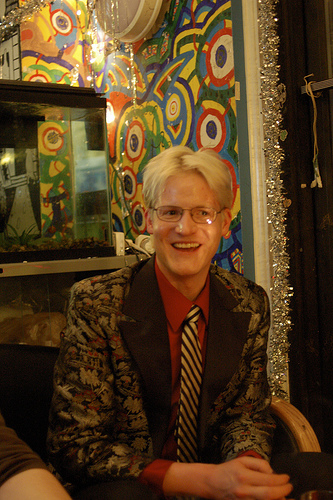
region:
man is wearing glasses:
[146, 204, 230, 225]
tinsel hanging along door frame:
[256, 0, 295, 399]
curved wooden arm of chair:
[267, 393, 319, 466]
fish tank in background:
[0, 267, 115, 352]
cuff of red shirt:
[137, 457, 194, 498]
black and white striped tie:
[178, 301, 205, 473]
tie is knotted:
[180, 301, 202, 324]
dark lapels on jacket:
[123, 257, 245, 454]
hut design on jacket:
[66, 341, 111, 376]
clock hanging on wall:
[94, 0, 171, 46]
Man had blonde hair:
[144, 141, 234, 207]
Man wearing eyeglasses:
[152, 205, 226, 224]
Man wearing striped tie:
[176, 302, 203, 461]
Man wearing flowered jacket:
[54, 262, 272, 479]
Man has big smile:
[169, 238, 206, 253]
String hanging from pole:
[297, 73, 327, 189]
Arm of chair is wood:
[274, 392, 325, 499]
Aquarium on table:
[3, 77, 114, 255]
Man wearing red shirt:
[147, 261, 211, 469]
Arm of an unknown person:
[0, 414, 70, 499]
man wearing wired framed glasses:
[149, 195, 222, 230]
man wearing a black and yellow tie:
[170, 289, 215, 481]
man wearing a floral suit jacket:
[55, 283, 270, 468]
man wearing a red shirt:
[143, 274, 237, 390]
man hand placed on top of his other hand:
[182, 435, 278, 498]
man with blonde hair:
[125, 124, 232, 215]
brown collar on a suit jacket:
[113, 280, 186, 444]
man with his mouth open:
[160, 229, 218, 260]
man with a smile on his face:
[165, 237, 209, 257]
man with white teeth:
[169, 238, 207, 253]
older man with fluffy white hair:
[44, 141, 294, 498]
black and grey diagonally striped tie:
[174, 296, 203, 462]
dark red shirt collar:
[146, 256, 213, 332]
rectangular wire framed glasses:
[146, 203, 232, 225]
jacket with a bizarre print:
[35, 257, 277, 488]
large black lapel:
[113, 250, 254, 456]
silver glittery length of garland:
[251, 0, 300, 400]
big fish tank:
[0, 77, 122, 263]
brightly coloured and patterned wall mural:
[12, 1, 244, 275]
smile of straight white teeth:
[166, 236, 205, 253]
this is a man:
[128, 276, 235, 385]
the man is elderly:
[118, 282, 264, 441]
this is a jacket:
[31, 309, 66, 388]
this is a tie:
[134, 361, 237, 473]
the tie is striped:
[153, 400, 211, 474]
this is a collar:
[163, 311, 172, 320]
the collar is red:
[159, 292, 167, 355]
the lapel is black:
[91, 320, 162, 417]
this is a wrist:
[175, 458, 204, 489]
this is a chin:
[151, 240, 216, 288]